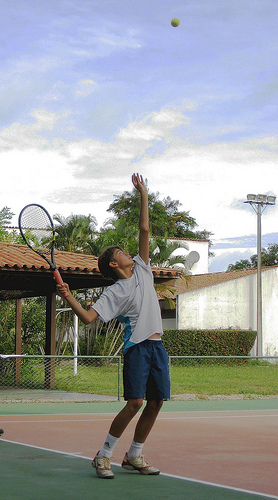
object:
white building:
[58, 236, 275, 361]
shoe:
[122, 452, 161, 475]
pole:
[118, 355, 121, 401]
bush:
[167, 319, 259, 361]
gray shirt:
[90, 254, 164, 352]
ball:
[171, 18, 180, 27]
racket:
[18, 202, 70, 296]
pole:
[256, 202, 262, 360]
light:
[246, 194, 255, 201]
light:
[257, 193, 267, 200]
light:
[267, 191, 276, 202]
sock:
[100, 433, 120, 460]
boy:
[55, 173, 170, 480]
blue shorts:
[123, 338, 170, 402]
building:
[0, 235, 278, 364]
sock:
[127, 438, 145, 460]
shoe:
[91, 449, 115, 479]